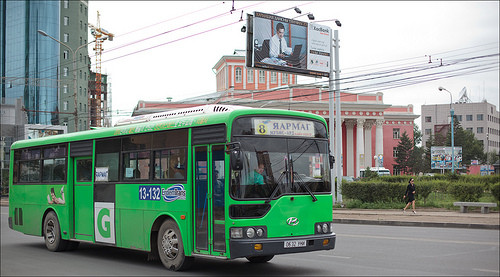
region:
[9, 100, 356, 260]
a green bus on a road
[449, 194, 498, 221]
a bench next to a road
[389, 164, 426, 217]
a woman walking next to a road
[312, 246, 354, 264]
a white stripe on a road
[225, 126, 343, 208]
a windshield on a bus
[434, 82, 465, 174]
a tall streetlight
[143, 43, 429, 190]
a large red brick building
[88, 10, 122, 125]
a construction crane alongside a building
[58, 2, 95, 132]
a tall gray building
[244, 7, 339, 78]
an advertisement next to a road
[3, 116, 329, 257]
this is a bus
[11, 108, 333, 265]
the bus is green in color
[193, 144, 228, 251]
the door is closed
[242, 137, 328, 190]
this is front screen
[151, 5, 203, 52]
this is electric wires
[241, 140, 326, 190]
the screen is clear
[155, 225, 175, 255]
this is a wheel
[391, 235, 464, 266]
this is a road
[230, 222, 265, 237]
the front light is off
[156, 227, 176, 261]
the wheel is dusty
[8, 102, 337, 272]
Green bus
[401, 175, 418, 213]
Woman in black outfit walking on a sidewalk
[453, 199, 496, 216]
Gray stone bench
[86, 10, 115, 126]
Construction crane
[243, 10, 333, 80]
Billboard with an advertisement next to a road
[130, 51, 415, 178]
Red and white building with white pillars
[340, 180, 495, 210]
Row of hedges next to a sidewalk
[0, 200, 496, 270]
Road with a bus on it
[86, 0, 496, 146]
Gray sky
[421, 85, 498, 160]
A tan building with a satellite dish on top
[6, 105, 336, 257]
green bus with blue sticker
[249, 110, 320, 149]
white sign with blue lettering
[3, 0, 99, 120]
tall building with several dozen windows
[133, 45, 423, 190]
pink building with white columns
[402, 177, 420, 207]
woman wearing black dress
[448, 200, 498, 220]
concrete bench on sidewalk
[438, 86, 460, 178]
light blue light pole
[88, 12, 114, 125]
orange construction crane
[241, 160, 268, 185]
person wearing teal shirt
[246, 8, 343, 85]
white billboard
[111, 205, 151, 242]
the bus is green in color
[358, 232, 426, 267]
this is the road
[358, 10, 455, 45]
this is the sky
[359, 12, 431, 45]
the sky has some clouds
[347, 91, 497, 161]
these are some buildings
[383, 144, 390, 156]
the wall is pink in color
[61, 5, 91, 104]
these are several windows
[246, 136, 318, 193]
this is a windscreen